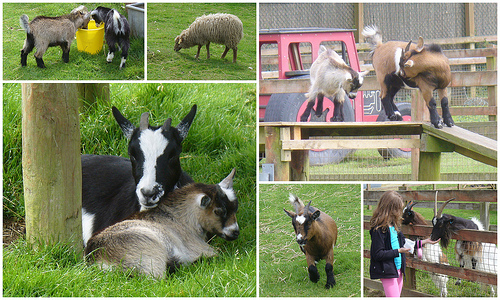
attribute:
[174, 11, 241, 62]
sheep — one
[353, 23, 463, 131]
goat — brown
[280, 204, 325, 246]
goat head — brown, white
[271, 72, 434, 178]
tires — gray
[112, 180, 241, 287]
brown/white goat — brown and white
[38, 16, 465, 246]
photos — six, different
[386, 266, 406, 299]
pants — pink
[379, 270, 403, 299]
pants — pink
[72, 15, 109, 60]
bucket — yellow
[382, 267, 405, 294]
pants — pink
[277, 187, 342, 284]
goat — brown, white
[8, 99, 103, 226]
pole — wooden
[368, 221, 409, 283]
jacket — black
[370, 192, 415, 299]
girl — one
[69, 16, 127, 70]
bucket — yellow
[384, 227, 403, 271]
shirt — blue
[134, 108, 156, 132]
horn — gray